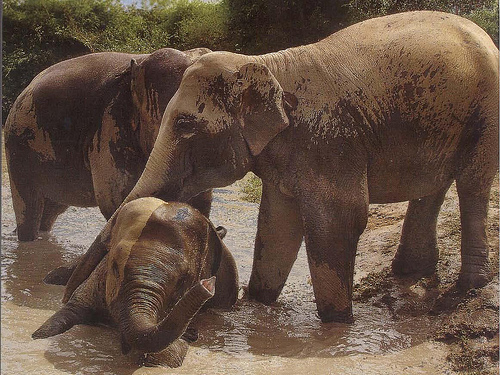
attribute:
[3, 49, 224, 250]
elephant — pictured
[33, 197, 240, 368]
elephant — pictured, brown, grey, playing, baby, lying down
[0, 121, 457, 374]
water — brown, dirty, muddy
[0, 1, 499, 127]
leaves — green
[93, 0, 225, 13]
sky — blue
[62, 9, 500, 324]
elephant — big, standing, pictured